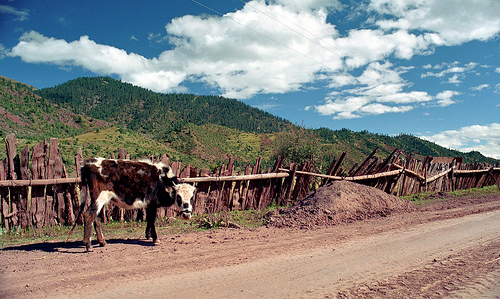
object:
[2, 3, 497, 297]
scene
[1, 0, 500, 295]
countryside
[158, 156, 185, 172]
fence board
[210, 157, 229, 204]
sticks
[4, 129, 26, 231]
stick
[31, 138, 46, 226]
stick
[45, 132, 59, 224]
stick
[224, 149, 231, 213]
stick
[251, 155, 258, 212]
stick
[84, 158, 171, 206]
brown spot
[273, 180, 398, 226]
mound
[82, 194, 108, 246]
legs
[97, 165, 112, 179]
hair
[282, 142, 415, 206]
leaning fence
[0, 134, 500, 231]
board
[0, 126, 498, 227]
fence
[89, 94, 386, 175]
grass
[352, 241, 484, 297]
tracks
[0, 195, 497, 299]
dirt road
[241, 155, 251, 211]
sticks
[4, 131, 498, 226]
elephant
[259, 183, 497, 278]
dirt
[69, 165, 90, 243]
tail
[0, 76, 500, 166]
mountain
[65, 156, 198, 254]
cow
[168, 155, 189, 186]
sticks